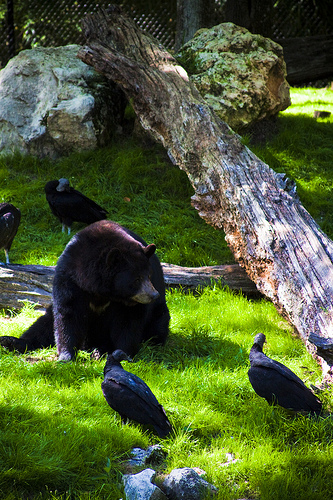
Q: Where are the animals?
A: In the grass.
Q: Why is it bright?
A: Sun is out.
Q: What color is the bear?
A: Brown.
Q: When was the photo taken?
A: Daytime.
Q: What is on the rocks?
A: Tree.